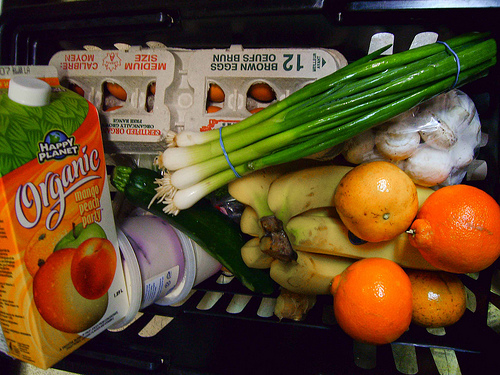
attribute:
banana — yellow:
[267, 164, 437, 224]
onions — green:
[150, 32, 499, 214]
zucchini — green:
[106, 162, 271, 290]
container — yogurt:
[115, 214, 178, 310]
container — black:
[214, 284, 294, 372]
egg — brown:
[249, 75, 274, 102]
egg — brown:
[199, 78, 227, 101]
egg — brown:
[104, 78, 124, 98]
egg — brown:
[146, 83, 157, 99]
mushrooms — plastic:
[344, 85, 491, 196]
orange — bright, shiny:
[329, 157, 419, 247]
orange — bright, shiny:
[406, 172, 498, 282]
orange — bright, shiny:
[322, 254, 424, 347]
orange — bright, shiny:
[402, 267, 476, 327]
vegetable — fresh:
[371, 119, 423, 162]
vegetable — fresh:
[408, 100, 458, 152]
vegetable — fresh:
[400, 142, 456, 190]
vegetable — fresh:
[144, 29, 488, 221]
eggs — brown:
[46, 40, 348, 158]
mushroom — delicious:
[409, 143, 452, 183]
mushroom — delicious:
[380, 119, 417, 159]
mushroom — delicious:
[423, 105, 469, 146]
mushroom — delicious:
[440, 91, 480, 128]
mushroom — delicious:
[451, 138, 474, 163]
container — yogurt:
[0, 64, 143, 368]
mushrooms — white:
[359, 73, 460, 185]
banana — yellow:
[265, 248, 345, 291]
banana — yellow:
[282, 206, 423, 266]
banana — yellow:
[239, 231, 276, 270]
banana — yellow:
[225, 167, 275, 229]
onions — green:
[155, 73, 445, 214]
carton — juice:
[11, 61, 133, 373]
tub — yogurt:
[117, 214, 184, 330]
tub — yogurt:
[157, 224, 220, 308]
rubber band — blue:
[211, 116, 243, 176]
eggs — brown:
[35, 34, 350, 163]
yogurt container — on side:
[168, 233, 228, 307]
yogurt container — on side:
[108, 208, 191, 328]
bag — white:
[366, 88, 490, 175]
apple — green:
[49, 218, 111, 248]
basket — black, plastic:
[3, 5, 492, 373]